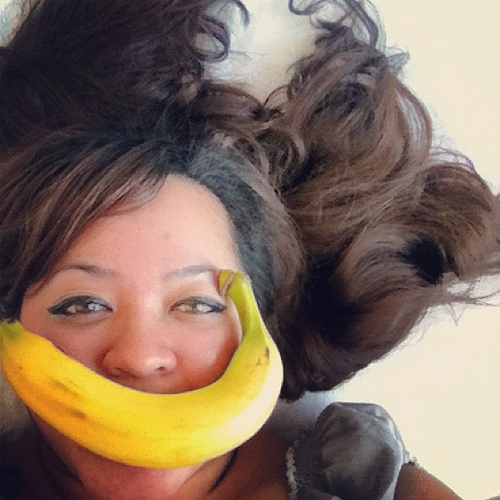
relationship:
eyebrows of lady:
[165, 261, 219, 279] [0, 3, 496, 499]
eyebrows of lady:
[25, 261, 118, 298] [0, 3, 496, 499]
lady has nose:
[0, 3, 496, 499] [109, 310, 169, 372]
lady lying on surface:
[0, 3, 496, 499] [6, 0, 498, 498]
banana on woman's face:
[15, 271, 295, 476] [16, 173, 253, 495]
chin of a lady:
[69, 453, 233, 498] [0, 3, 496, 499]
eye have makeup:
[54, 295, 110, 318] [45, 295, 116, 315]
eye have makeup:
[167, 298, 222, 315] [176, 292, 228, 312]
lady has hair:
[0, 3, 496, 499] [48, 43, 355, 178]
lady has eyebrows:
[0, 3, 496, 499] [36, 255, 213, 286]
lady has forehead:
[0, 3, 496, 499] [65, 170, 230, 277]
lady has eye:
[0, 3, 496, 499] [170, 298, 226, 316]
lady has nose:
[0, 3, 496, 499] [101, 326, 177, 378]